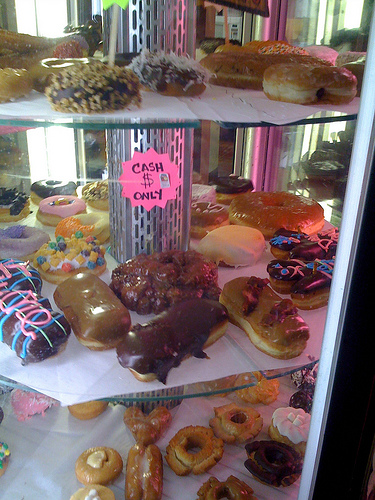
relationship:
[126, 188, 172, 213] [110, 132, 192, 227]
only on sign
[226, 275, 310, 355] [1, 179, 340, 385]
bar on tray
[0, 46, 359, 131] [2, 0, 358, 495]
tray protects glass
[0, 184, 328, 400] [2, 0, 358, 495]
tray protects glass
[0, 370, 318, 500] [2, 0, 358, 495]
tray protects glass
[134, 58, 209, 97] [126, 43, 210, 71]
doughnut has coconut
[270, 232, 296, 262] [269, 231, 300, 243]
cupcake has icing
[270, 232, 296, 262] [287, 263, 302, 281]
cupcake has icing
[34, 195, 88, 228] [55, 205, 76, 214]
doughnut has icing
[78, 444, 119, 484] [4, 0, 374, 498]
donut on display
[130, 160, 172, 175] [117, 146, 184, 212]
cash on sign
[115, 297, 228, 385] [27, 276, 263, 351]
eclair in pastry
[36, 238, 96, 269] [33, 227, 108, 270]
donut with cereal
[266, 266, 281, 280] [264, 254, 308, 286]
frosting on pastry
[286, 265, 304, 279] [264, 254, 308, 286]
icing on pastry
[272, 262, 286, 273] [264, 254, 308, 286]
blue decorations on pastry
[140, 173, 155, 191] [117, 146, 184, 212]
dollar sign on sign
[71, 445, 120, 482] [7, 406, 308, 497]
pastry on tray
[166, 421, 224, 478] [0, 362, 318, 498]
donut on tray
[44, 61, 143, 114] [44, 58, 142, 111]
doughnut covered with nuts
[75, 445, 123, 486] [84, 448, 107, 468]
donut has filling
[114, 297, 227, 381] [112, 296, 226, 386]
eclair has frosting